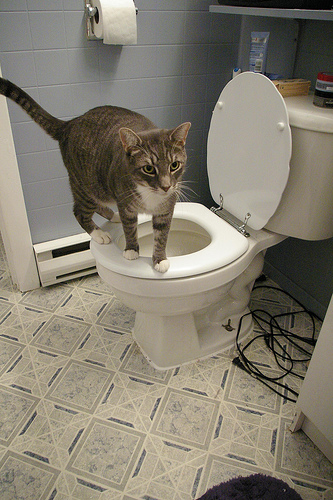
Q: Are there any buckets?
A: No, there are no buckets.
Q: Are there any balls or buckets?
A: No, there are no buckets or balls.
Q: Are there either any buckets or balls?
A: No, there are no buckets or balls.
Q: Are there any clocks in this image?
A: No, there are no clocks.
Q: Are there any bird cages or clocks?
A: No, there are no clocks or bird cages.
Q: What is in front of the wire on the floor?
A: The toilet is in front of the wire.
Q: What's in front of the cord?
A: The toilet is in front of the wire.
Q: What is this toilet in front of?
A: The toilet is in front of the cord.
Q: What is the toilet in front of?
A: The toilet is in front of the cord.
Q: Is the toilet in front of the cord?
A: Yes, the toilet is in front of the cord.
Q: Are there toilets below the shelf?
A: Yes, there is a toilet below the shelf.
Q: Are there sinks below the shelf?
A: No, there is a toilet below the shelf.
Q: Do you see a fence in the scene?
A: No, there are no fences.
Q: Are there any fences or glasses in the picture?
A: No, there are no fences or glasses.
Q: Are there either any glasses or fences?
A: No, there are no fences or glasses.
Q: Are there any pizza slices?
A: No, there are no pizza slices.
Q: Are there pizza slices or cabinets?
A: No, there are no pizza slices or cabinets.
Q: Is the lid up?
A: Yes, the lid is up.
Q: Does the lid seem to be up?
A: Yes, the lid is up.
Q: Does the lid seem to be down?
A: No, the lid is up.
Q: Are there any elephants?
A: No, there are no elephants.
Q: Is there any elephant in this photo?
A: No, there are no elephants.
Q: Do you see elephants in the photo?
A: No, there are no elephants.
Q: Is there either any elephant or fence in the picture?
A: No, there are no elephants or fences.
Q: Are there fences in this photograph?
A: No, there are no fences.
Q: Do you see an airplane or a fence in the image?
A: No, there are no fences or airplanes.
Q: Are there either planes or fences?
A: No, there are no fences or planes.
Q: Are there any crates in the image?
A: No, there are no crates.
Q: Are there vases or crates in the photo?
A: No, there are no crates or vases.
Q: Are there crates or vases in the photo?
A: No, there are no crates or vases.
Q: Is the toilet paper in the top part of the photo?
A: Yes, the toilet paper is in the top of the image.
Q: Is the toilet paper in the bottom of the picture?
A: No, the toilet paper is in the top of the image.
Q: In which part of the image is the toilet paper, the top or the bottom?
A: The toilet paper is in the top of the image.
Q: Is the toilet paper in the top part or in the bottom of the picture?
A: The toilet paper is in the top of the image.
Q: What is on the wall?
A: The toilet paper is on the wall.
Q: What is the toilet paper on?
A: The toilet paper is on the wall.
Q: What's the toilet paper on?
A: The toilet paper is on the wall.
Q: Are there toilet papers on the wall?
A: Yes, there is a toilet paper on the wall.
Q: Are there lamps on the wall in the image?
A: No, there is a toilet paper on the wall.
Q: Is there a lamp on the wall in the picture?
A: No, there is a toilet paper on the wall.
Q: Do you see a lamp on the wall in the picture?
A: No, there is a toilet paper on the wall.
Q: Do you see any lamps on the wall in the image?
A: No, there is a toilet paper on the wall.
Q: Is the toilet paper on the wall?
A: Yes, the toilet paper is on the wall.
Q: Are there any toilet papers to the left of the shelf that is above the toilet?
A: Yes, there is a toilet paper to the left of the shelf.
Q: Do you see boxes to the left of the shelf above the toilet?
A: No, there is a toilet paper to the left of the shelf.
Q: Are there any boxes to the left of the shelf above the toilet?
A: No, there is a toilet paper to the left of the shelf.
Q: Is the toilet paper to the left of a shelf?
A: Yes, the toilet paper is to the left of a shelf.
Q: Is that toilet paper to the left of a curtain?
A: No, the toilet paper is to the left of a shelf.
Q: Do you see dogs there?
A: No, there are no dogs.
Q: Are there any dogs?
A: No, there are no dogs.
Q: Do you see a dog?
A: No, there are no dogs.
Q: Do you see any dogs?
A: No, there are no dogs.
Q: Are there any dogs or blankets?
A: No, there are no dogs or blankets.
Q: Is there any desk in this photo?
A: No, there are no desks.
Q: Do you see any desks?
A: No, there are no desks.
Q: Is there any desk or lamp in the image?
A: No, there are no desks or lamps.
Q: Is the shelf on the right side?
A: Yes, the shelf is on the right of the image.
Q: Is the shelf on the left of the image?
A: No, the shelf is on the right of the image.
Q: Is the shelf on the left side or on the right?
A: The shelf is on the right of the image.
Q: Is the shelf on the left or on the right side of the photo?
A: The shelf is on the right of the image.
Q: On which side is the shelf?
A: The shelf is on the right of the image.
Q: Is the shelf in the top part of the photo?
A: Yes, the shelf is in the top of the image.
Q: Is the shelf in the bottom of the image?
A: No, the shelf is in the top of the image.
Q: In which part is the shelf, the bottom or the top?
A: The shelf is in the top of the image.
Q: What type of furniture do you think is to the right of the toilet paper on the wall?
A: The piece of furniture is a shelf.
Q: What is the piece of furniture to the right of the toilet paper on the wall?
A: The piece of furniture is a shelf.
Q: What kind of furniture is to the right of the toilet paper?
A: The piece of furniture is a shelf.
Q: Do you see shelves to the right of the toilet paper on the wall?
A: Yes, there is a shelf to the right of the toilet paper.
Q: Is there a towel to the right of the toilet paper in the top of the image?
A: No, there is a shelf to the right of the toilet paper.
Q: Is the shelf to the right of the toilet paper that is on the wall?
A: Yes, the shelf is to the right of the toilet paper.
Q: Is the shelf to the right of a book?
A: No, the shelf is to the right of the toilet paper.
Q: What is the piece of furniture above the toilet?
A: The piece of furniture is a shelf.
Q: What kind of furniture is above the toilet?
A: The piece of furniture is a shelf.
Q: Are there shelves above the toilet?
A: Yes, there is a shelf above the toilet.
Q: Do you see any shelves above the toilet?
A: Yes, there is a shelf above the toilet.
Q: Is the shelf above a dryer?
A: No, the shelf is above the toilet.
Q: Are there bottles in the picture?
A: Yes, there is a bottle.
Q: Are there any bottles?
A: Yes, there is a bottle.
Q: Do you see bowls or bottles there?
A: Yes, there is a bottle.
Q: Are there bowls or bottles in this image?
A: Yes, there is a bottle.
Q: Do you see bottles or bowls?
A: Yes, there is a bottle.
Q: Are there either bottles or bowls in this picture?
A: Yes, there is a bottle.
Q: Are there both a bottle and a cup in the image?
A: No, there is a bottle but no cups.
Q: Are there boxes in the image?
A: No, there are no boxes.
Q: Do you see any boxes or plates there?
A: No, there are no boxes or plates.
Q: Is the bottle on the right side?
A: Yes, the bottle is on the right of the image.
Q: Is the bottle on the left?
A: No, the bottle is on the right of the image.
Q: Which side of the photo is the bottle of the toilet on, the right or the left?
A: The bottle is on the right of the image.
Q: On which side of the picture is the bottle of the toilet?
A: The bottle is on the right of the image.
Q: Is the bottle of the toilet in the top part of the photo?
A: Yes, the bottle is in the top of the image.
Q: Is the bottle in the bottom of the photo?
A: No, the bottle is in the top of the image.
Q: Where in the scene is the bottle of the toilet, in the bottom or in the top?
A: The bottle is in the top of the image.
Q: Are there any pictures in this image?
A: No, there are no pictures.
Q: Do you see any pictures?
A: No, there are no pictures.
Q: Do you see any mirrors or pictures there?
A: No, there are no pictures or mirrors.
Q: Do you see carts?
A: No, there are no carts.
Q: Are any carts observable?
A: No, there are no carts.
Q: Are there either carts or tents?
A: No, there are no carts or tents.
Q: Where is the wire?
A: The wire is on the floor.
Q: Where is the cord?
A: The wire is on the floor.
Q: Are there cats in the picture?
A: Yes, there is a cat.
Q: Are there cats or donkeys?
A: Yes, there is a cat.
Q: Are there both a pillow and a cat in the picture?
A: No, there is a cat but no pillows.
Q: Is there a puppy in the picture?
A: No, there are no puppys.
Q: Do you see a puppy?
A: No, there are no puppys.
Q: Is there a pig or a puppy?
A: No, there are no puppys or pigs.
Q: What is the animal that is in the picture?
A: The animal is a cat.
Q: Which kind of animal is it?
A: The animal is a cat.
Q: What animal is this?
A: This is a cat.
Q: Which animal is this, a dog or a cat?
A: This is a cat.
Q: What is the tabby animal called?
A: The animal is a cat.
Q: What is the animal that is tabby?
A: The animal is a cat.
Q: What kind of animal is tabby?
A: The animal is a cat.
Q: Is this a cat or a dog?
A: This is a cat.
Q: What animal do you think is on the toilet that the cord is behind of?
A: The cat is on the toilet.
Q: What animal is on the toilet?
A: The cat is on the toilet.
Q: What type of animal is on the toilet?
A: The animal is a cat.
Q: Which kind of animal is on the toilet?
A: The animal is a cat.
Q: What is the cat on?
A: The cat is on the toilet.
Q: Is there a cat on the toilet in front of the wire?
A: Yes, there is a cat on the toilet.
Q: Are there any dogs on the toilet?
A: No, there is a cat on the toilet.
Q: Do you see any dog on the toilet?
A: No, there is a cat on the toilet.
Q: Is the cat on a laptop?
A: No, the cat is on the toilet.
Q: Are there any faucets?
A: No, there are no faucets.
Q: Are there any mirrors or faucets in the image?
A: No, there are no faucets or mirrors.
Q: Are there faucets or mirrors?
A: No, there are no faucets or mirrors.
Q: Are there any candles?
A: No, there are no candles.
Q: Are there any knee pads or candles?
A: No, there are no candles or knee pads.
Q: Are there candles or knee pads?
A: No, there are no candles or knee pads.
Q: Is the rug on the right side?
A: Yes, the rug is on the right of the image.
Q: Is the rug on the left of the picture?
A: No, the rug is on the right of the image.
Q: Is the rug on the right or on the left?
A: The rug is on the right of the image.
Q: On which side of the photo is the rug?
A: The rug is on the right of the image.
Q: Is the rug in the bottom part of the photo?
A: Yes, the rug is in the bottom of the image.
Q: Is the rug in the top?
A: No, the rug is in the bottom of the image.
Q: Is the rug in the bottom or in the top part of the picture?
A: The rug is in the bottom of the image.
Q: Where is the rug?
A: The rug is on the floor.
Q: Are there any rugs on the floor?
A: Yes, there is a rug on the floor.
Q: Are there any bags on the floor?
A: No, there is a rug on the floor.